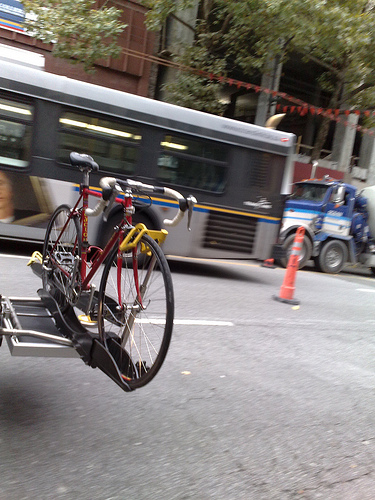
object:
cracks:
[286, 443, 375, 500]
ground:
[298, 124, 336, 153]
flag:
[237, 79, 241, 88]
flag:
[276, 104, 280, 110]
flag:
[290, 106, 296, 114]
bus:
[0, 60, 297, 269]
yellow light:
[0, 102, 192, 152]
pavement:
[0, 253, 373, 497]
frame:
[73, 181, 149, 307]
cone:
[270, 223, 307, 303]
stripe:
[292, 241, 303, 247]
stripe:
[290, 250, 305, 256]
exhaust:
[264, 113, 286, 131]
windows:
[153, 134, 229, 195]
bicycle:
[43, 151, 196, 387]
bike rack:
[0, 284, 138, 394]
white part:
[290, 239, 301, 256]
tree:
[24, 1, 131, 73]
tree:
[162, 44, 225, 110]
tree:
[139, 1, 375, 119]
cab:
[273, 176, 375, 273]